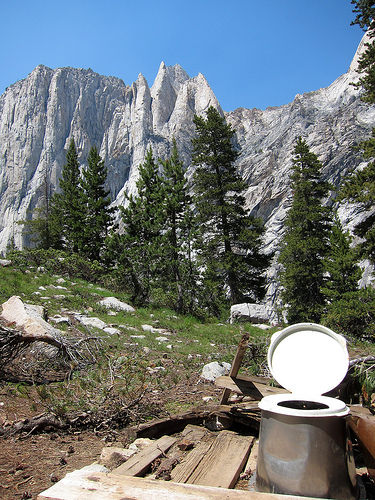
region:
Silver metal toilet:
[249, 321, 354, 498]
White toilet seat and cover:
[252, 320, 354, 418]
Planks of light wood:
[108, 418, 261, 489]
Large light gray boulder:
[225, 300, 269, 330]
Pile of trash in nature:
[37, 323, 373, 499]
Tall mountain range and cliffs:
[0, 11, 374, 327]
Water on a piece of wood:
[231, 466, 259, 491]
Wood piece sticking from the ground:
[217, 330, 250, 403]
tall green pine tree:
[187, 105, 276, 314]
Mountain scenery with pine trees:
[1, 0, 374, 337]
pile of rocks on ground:
[1, 279, 101, 393]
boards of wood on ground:
[116, 393, 233, 498]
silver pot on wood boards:
[256, 322, 372, 499]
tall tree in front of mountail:
[178, 97, 272, 310]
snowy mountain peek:
[126, 45, 258, 143]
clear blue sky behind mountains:
[121, 2, 249, 124]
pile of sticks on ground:
[4, 376, 144, 430]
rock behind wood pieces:
[185, 323, 274, 411]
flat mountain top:
[6, 35, 129, 123]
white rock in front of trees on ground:
[217, 267, 289, 340]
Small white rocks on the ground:
[19, 262, 49, 276]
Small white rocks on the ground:
[3, 252, 15, 270]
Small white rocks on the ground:
[99, 293, 132, 316]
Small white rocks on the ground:
[135, 312, 174, 343]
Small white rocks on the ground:
[121, 330, 151, 353]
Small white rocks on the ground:
[77, 310, 123, 349]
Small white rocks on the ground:
[196, 354, 237, 389]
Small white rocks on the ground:
[127, 341, 161, 379]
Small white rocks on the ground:
[110, 303, 176, 353]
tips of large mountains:
[0, 46, 211, 122]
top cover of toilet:
[262, 320, 349, 392]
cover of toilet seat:
[260, 322, 350, 385]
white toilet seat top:
[252, 392, 345, 413]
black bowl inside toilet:
[285, 395, 323, 412]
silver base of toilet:
[255, 411, 345, 493]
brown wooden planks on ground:
[162, 425, 258, 494]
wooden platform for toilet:
[128, 434, 245, 497]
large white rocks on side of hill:
[0, 291, 76, 337]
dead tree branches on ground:
[0, 372, 135, 442]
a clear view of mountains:
[28, 43, 370, 318]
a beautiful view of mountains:
[12, 15, 363, 192]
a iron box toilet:
[256, 400, 356, 493]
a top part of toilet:
[270, 323, 355, 384]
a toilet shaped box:
[228, 300, 358, 493]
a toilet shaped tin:
[225, 298, 368, 496]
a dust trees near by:
[15, 325, 179, 438]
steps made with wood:
[125, 422, 257, 489]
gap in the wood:
[214, 423, 266, 497]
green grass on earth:
[127, 285, 231, 335]